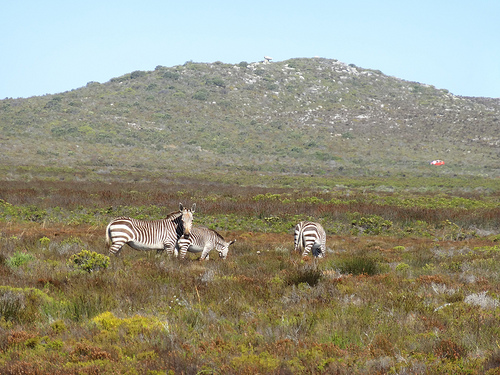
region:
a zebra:
[292, 219, 334, 264]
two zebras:
[105, 205, 237, 260]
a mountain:
[104, 65, 380, 162]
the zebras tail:
[100, 228, 115, 246]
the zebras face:
[182, 212, 196, 237]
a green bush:
[70, 248, 112, 270]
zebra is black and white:
[292, 220, 332, 255]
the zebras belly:
[132, 238, 165, 250]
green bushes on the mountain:
[239, 125, 326, 157]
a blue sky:
[26, 8, 127, 69]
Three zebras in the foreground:
[89, 181, 364, 293]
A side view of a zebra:
[100, 190, 204, 270]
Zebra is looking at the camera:
[171, 193, 202, 243]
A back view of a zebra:
[286, 210, 331, 268]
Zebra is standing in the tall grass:
[73, 245, 222, 315]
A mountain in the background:
[3, 28, 499, 185]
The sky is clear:
[4, 3, 498, 95]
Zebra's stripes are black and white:
[103, 195, 335, 279]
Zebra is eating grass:
[212, 230, 243, 275]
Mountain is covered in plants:
[3, 46, 499, 167]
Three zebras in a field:
[96, 190, 329, 276]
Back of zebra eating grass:
[276, 212, 345, 295]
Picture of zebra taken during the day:
[81, 48, 338, 319]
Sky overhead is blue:
[80, 0, 431, 112]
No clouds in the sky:
[6, 0, 488, 174]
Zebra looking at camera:
[168, 192, 195, 259]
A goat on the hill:
[253, 51, 278, 75]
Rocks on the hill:
[297, 57, 374, 98]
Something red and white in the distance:
[393, 148, 458, 174]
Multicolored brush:
[11, 278, 177, 348]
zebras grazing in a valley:
[41, 191, 403, 293]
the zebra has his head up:
[100, 198, 198, 274]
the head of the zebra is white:
[177, 198, 197, 241]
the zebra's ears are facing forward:
[176, 196, 198, 215]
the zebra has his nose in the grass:
[197, 223, 239, 270]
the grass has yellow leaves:
[82, 303, 174, 353]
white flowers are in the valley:
[162, 288, 189, 315]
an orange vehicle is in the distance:
[424, 155, 450, 173]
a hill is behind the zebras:
[1, 50, 499, 277]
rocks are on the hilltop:
[223, 46, 360, 91]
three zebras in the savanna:
[99, 196, 339, 264]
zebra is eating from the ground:
[283, 213, 331, 276]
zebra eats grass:
[179, 217, 242, 269]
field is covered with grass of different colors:
[0, 166, 496, 373]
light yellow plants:
[89, 308, 174, 340]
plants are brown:
[71, 191, 493, 220]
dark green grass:
[336, 248, 383, 281]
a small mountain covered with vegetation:
[19, 48, 497, 155]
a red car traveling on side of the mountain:
[422, 148, 453, 171]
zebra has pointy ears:
[174, 197, 198, 242]